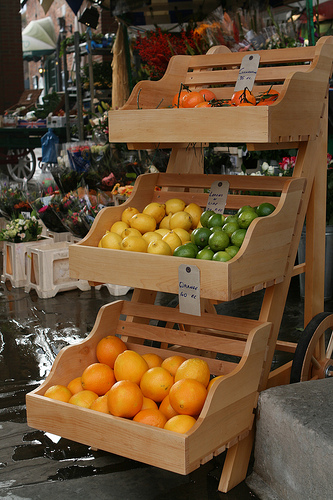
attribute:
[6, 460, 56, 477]
floor — wooden 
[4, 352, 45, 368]
floor — wet 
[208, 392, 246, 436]
shelf — wooden 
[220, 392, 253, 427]
shelf — brown  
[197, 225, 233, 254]
lemons — green 